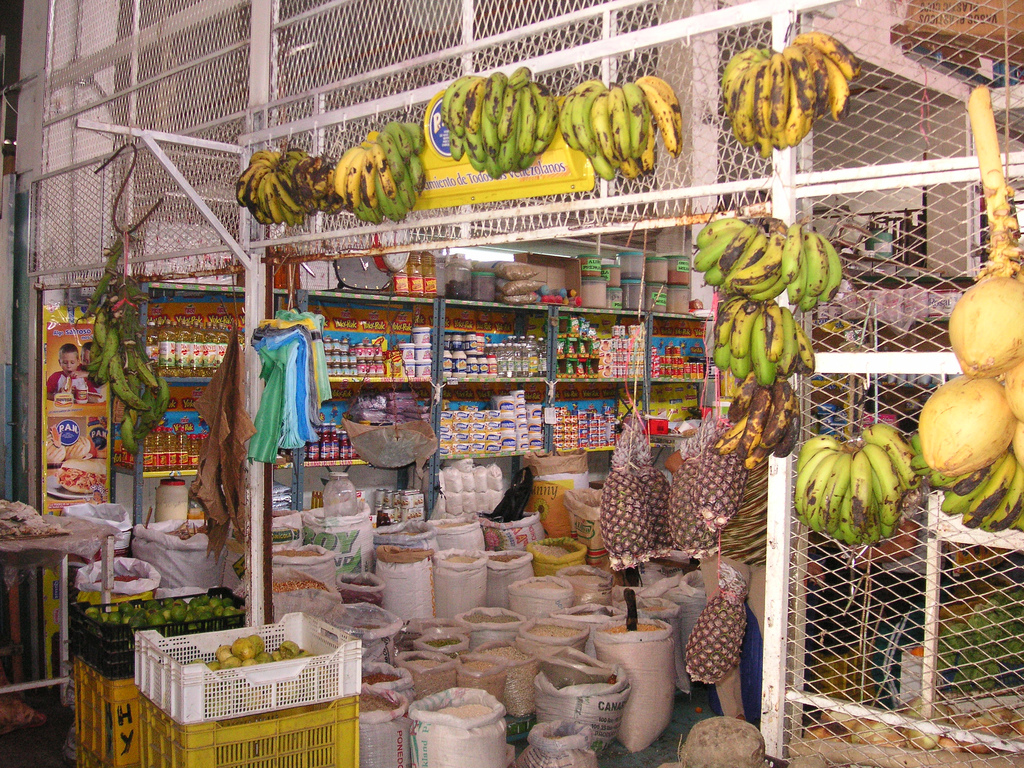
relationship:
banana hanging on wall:
[798, 33, 862, 84] [27, 7, 1016, 767]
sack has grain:
[408, 685, 503, 766] [429, 702, 497, 720]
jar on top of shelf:
[578, 276, 609, 310] [111, 282, 712, 526]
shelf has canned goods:
[111, 282, 712, 526] [554, 404, 581, 450]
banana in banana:
[798, 33, 862, 84] [722, 32, 862, 158]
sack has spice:
[595, 617, 678, 752] [608, 621, 662, 635]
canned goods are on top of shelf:
[554, 404, 581, 450] [111, 282, 712, 526]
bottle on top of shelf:
[152, 423, 168, 474] [111, 282, 712, 526]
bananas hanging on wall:
[427, 67, 562, 177] [27, 7, 1016, 767]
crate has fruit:
[72, 586, 255, 678] [168, 602, 188, 624]